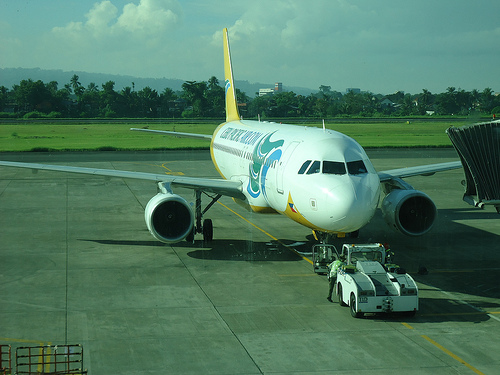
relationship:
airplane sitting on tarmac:
[0, 25, 463, 246] [1, 148, 499, 374]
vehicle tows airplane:
[311, 242, 420, 318] [0, 25, 463, 246]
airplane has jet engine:
[0, 25, 463, 246] [143, 192, 195, 243]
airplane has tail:
[0, 25, 463, 246] [221, 27, 242, 121]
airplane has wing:
[0, 25, 463, 246] [0, 158, 244, 201]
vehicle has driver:
[311, 242, 420, 318] [325, 255, 345, 303]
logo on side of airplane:
[246, 129, 284, 199] [0, 25, 463, 246]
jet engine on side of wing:
[143, 192, 195, 243] [0, 158, 244, 201]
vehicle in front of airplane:
[311, 242, 420, 318] [0, 25, 463, 246]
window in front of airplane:
[321, 160, 346, 176] [0, 25, 463, 246]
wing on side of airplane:
[376, 161, 465, 182] [0, 25, 463, 246]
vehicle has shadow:
[311, 242, 420, 318] [360, 297, 499, 324]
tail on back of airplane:
[221, 27, 242, 121] [0, 25, 463, 246]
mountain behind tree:
[0, 66, 321, 97] [70, 74, 81, 90]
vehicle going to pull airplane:
[311, 242, 420, 318] [0, 25, 463, 246]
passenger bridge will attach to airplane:
[444, 118, 500, 208] [0, 25, 463, 246]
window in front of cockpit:
[346, 159, 369, 175] [298, 157, 376, 176]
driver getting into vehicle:
[325, 255, 345, 303] [311, 242, 420, 318]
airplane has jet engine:
[0, 25, 463, 246] [380, 187, 438, 237]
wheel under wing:
[201, 218, 213, 243] [0, 158, 244, 201]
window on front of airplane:
[321, 160, 346, 176] [0, 25, 463, 246]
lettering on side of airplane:
[218, 127, 263, 146] [0, 25, 463, 246]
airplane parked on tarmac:
[0, 25, 463, 246] [1, 148, 499, 374]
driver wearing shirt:
[325, 255, 345, 303] [327, 260, 345, 279]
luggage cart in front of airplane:
[0, 342, 89, 375] [0, 25, 463, 246]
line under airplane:
[161, 160, 314, 265] [0, 25, 463, 246]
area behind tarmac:
[0, 122, 474, 153] [1, 148, 499, 374]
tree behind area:
[401, 93, 418, 116] [0, 122, 474, 153]